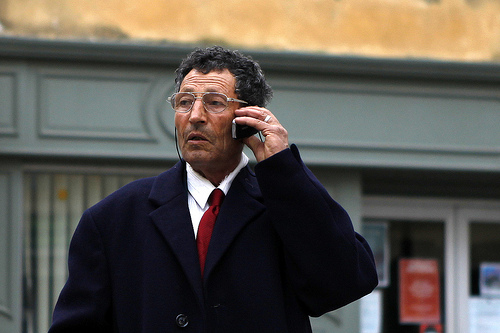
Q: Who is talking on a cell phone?
A: The man.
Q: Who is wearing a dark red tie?
A: The man.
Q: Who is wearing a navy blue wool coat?
A: The man.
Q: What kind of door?
A: Glass.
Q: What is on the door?
A: Signs.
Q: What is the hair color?
A: Dark.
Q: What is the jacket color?
A: Black.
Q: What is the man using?
A: Phone.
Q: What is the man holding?
A: Phone.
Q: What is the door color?
A: White.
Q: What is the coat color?
A: Blue.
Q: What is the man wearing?
A: Coat.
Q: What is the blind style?
A: Venetian.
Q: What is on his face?
A: Glasses.